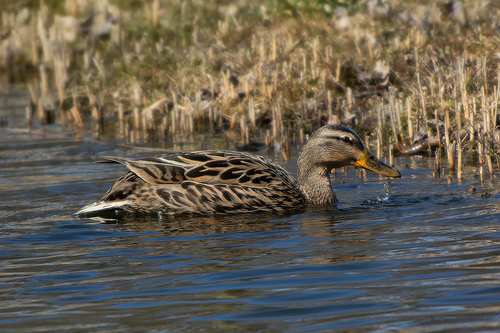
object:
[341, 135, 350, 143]
eye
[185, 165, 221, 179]
feathers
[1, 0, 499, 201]
grass reeds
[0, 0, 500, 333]
ground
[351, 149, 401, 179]
beak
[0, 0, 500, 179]
grass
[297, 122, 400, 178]
head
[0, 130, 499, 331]
water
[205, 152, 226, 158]
spots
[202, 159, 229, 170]
feathers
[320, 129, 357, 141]
stripe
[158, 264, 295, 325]
rippled water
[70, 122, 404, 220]
duck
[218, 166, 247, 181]
feathers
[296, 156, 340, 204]
neck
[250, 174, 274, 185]
feathers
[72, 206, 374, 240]
reflection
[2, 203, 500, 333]
water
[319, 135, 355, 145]
stripes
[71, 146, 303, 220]
body